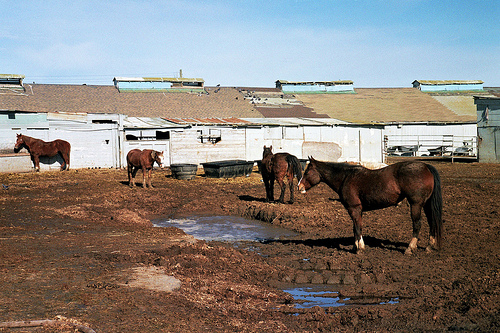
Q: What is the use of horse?
A: Travel.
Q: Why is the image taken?
A: Remembrance.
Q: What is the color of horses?
A: Brown.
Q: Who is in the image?
A: Horse.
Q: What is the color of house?
A: White.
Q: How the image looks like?
A: Good.